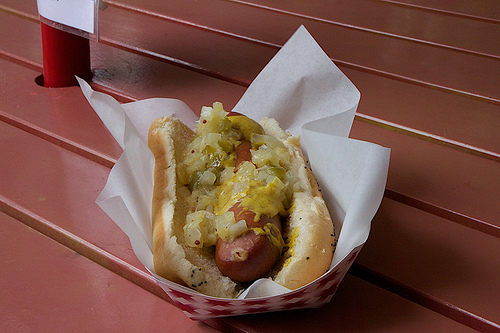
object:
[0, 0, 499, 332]
table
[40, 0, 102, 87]
pole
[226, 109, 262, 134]
mustard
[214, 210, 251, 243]
onions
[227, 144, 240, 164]
relish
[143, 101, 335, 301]
bun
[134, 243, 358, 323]
tray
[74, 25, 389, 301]
paper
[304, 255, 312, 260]
seeds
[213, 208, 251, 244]
toppings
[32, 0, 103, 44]
sign